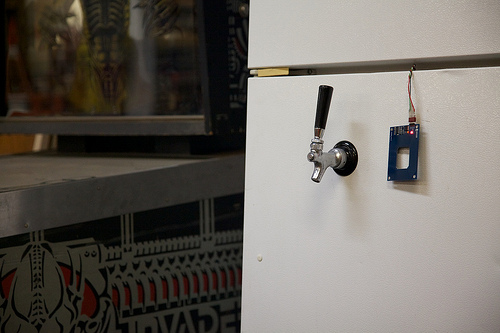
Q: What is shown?
A: Fridge.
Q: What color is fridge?
A: White.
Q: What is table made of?
A: Metal.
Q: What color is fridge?
A: White.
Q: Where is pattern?
A: Under counter.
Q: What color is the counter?
A: Silver.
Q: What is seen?
A: A wall.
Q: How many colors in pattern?
A: Three.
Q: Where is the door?
A: On the refrigerator.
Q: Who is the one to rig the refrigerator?
A: Engineer.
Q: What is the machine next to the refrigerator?
A: Pinball machine.